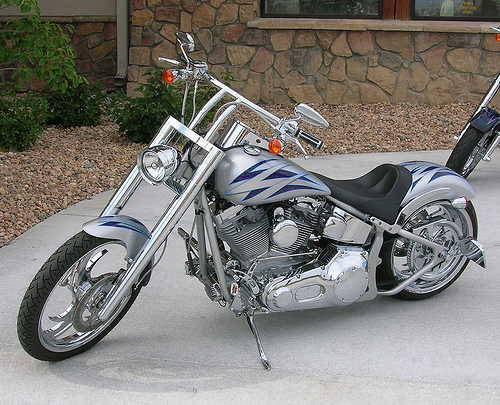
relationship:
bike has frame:
[15, 38, 493, 379] [90, 59, 451, 324]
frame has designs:
[90, 59, 451, 324] [216, 142, 331, 210]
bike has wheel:
[15, 31, 483, 374] [13, 230, 142, 364]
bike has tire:
[15, 31, 483, 374] [383, 196, 480, 297]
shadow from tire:
[47, 339, 285, 397] [15, 229, 142, 364]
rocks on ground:
[3, 97, 475, 243] [4, 103, 497, 403]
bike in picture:
[15, 31, 483, 374] [1, 2, 497, 402]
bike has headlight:
[15, 31, 483, 374] [130, 140, 186, 190]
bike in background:
[438, 21, 498, 178] [1, 2, 494, 179]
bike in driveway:
[15, 38, 493, 379] [0, 150, 498, 401]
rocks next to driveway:
[3, 97, 475, 243] [0, 150, 498, 401]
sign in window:
[414, 0, 494, 23] [262, 0, 477, 20]